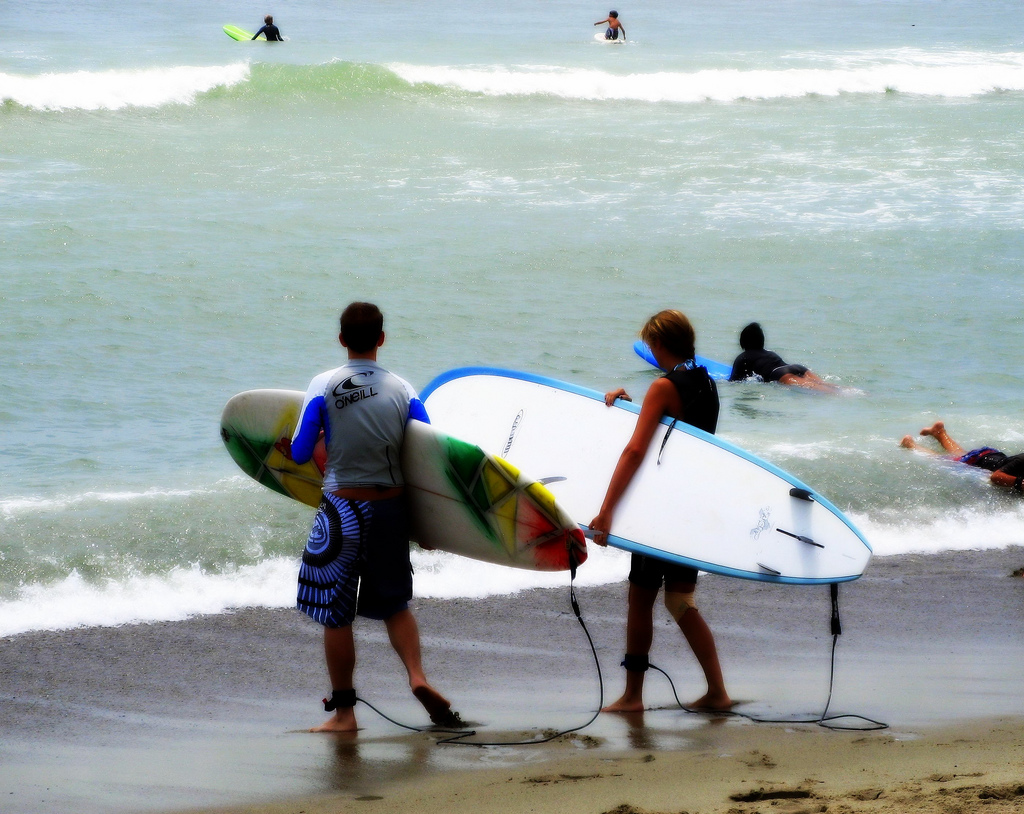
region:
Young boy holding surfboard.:
[218, 299, 591, 742]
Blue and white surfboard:
[403, 364, 878, 587]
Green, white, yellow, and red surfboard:
[220, 387, 588, 571]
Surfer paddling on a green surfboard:
[221, 13, 286, 51]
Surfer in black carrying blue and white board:
[413, 305, 873, 721]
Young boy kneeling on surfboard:
[590, 8, 628, 48]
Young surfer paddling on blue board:
[634, 320, 898, 412]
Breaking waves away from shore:
[2, 58, 1023, 115]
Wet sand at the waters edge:
[0, 536, 1021, 770]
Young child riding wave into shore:
[887, 418, 1023, 489]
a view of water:
[391, 111, 502, 207]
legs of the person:
[259, 617, 457, 725]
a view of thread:
[525, 679, 618, 796]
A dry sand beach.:
[349, 719, 1020, 811]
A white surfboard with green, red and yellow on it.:
[216, 387, 589, 569]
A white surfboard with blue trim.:
[409, 365, 875, 584]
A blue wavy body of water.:
[3, 1, 1022, 638]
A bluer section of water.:
[3, 2, 1021, 69]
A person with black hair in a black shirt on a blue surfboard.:
[731, 318, 840, 391]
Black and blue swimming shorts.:
[292, 487, 416, 625]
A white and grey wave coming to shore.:
[0, 424, 1015, 631]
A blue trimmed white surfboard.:
[418, 364, 871, 583]